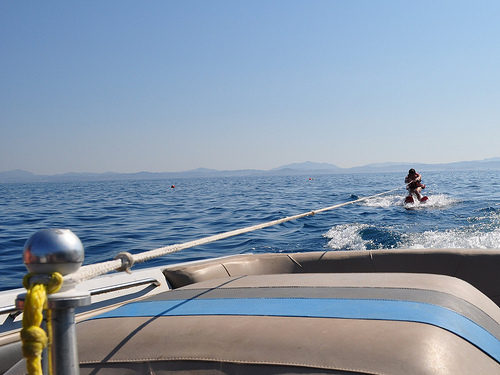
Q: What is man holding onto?
A: Long white rope for water skiing.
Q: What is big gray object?
A: Back of boat.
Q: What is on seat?
A: Blue strip of leather.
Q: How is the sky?
A: Clear blue sky.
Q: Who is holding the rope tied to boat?
A: The man.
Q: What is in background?
A: Mountains.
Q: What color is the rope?
A: White.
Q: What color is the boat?
A: Grey and blue.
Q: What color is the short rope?
A: Yellow.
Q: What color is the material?
A: Grey, dark grey, and blue.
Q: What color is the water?
A: Blue.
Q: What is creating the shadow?
A: The rope.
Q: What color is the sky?
A: White and light blue.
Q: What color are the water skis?
A: Red.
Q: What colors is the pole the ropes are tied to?
A: Silver.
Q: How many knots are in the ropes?
A: 2.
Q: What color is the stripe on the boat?
A: Blue.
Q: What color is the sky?
A: Blue.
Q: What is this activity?
A: Water skiing.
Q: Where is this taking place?
A: On the water.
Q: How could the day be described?
A: Sunny.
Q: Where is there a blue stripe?
A: On the boat.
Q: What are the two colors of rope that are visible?
A: Yellow and white.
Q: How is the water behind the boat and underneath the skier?
A: Frothy.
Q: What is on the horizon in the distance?
A: Mountains.